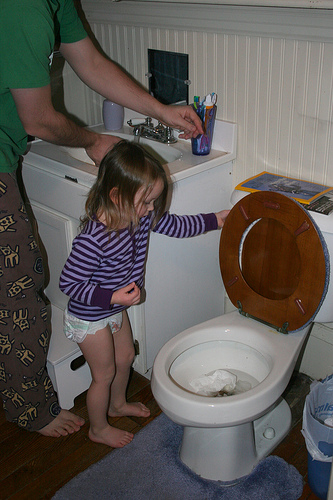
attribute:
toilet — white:
[149, 173, 333, 481]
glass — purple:
[189, 104, 217, 156]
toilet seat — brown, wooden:
[217, 190, 330, 333]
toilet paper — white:
[186, 368, 238, 394]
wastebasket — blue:
[302, 378, 332, 496]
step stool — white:
[47, 303, 92, 410]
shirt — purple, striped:
[56, 213, 219, 321]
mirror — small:
[145, 48, 190, 106]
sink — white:
[65, 130, 186, 167]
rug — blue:
[52, 413, 303, 499]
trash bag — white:
[301, 378, 333, 463]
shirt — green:
[0, 0, 90, 175]